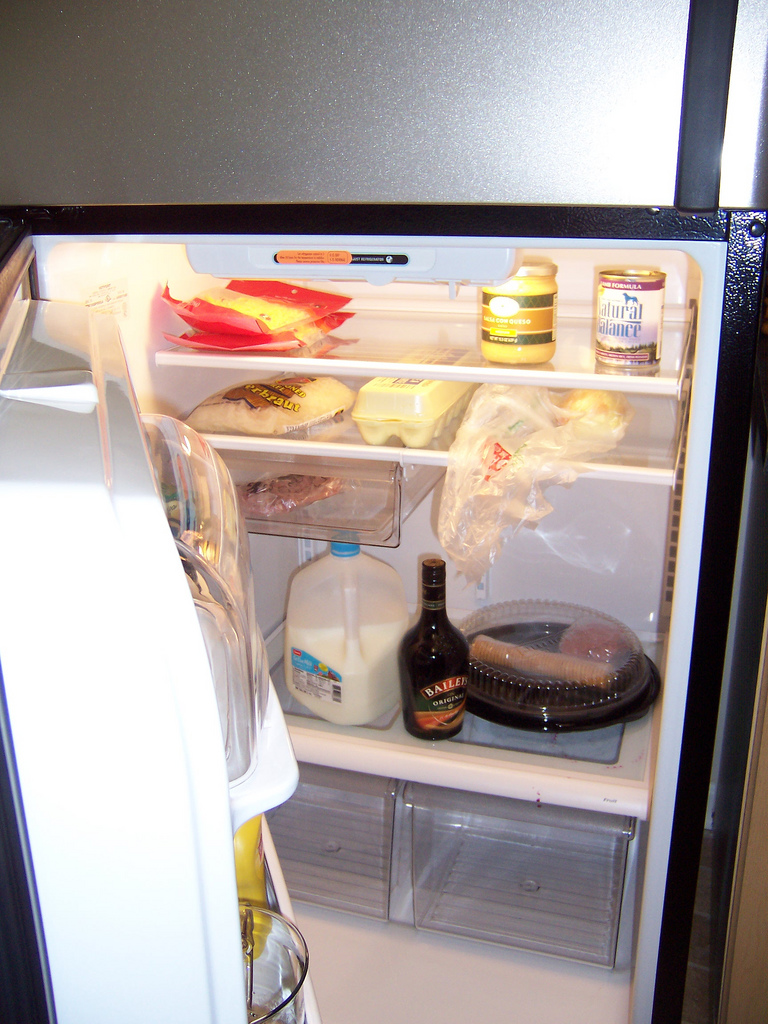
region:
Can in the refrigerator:
[585, 267, 671, 375]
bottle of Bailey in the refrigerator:
[396, 546, 479, 752]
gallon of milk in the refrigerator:
[262, 545, 412, 737]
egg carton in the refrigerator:
[348, 359, 453, 446]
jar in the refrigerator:
[464, 258, 553, 372]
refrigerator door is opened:
[2, 211, 704, 796]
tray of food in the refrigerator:
[453, 588, 654, 754]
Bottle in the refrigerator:
[390, 539, 495, 756]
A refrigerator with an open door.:
[0, 202, 764, 1020]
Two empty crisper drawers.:
[263, 759, 631, 966]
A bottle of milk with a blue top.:
[280, 539, 405, 721]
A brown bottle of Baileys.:
[393, 554, 466, 737]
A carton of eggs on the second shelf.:
[348, 340, 478, 444]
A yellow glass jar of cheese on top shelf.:
[477, 260, 554, 358]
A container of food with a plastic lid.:
[458, 596, 656, 728]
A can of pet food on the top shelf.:
[594, 266, 663, 365]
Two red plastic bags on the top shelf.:
[162, 279, 354, 352]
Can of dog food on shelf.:
[594, 274, 664, 370]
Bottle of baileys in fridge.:
[407, 559, 483, 744]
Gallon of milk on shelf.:
[278, 553, 416, 741]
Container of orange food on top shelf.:
[480, 276, 560, 367]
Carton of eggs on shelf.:
[361, 357, 466, 443]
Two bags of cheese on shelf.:
[189, 271, 336, 369]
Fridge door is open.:
[6, 247, 594, 784]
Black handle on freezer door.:
[672, 27, 737, 211]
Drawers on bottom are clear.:
[286, 781, 614, 954]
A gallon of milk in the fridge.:
[290, 542, 406, 729]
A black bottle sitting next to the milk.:
[408, 551, 473, 739]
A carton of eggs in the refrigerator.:
[358, 350, 465, 447]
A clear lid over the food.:
[477, 602, 643, 701]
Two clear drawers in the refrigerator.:
[295, 783, 660, 961]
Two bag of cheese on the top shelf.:
[178, 283, 337, 352]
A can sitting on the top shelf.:
[579, 268, 673, 375]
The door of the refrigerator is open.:
[21, 582, 295, 1021]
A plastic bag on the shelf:
[466, 385, 634, 480]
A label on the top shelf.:
[259, 247, 407, 287]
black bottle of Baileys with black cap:
[399, 559, 467, 738]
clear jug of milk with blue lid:
[285, 539, 405, 724]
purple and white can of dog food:
[594, 268, 664, 368]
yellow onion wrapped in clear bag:
[560, 388, 626, 442]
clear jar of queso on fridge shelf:
[480, 261, 556, 359]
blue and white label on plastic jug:
[287, 645, 341, 705]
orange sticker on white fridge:
[276, 249, 350, 266]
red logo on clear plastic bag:
[481, 437, 511, 483]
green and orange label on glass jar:
[478, 290, 556, 345]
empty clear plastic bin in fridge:
[399, 777, 637, 978]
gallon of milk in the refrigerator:
[280, 538, 419, 726]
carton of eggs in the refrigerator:
[350, 334, 479, 452]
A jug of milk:
[268, 504, 438, 742]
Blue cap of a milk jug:
[303, 516, 377, 568]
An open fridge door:
[0, 213, 384, 1013]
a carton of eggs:
[349, 377, 468, 446]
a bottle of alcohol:
[396, 555, 470, 742]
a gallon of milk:
[284, 534, 411, 726]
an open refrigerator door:
[4, 220, 766, 1022]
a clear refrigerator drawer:
[262, 757, 401, 919]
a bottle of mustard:
[231, 817, 269, 951]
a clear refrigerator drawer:
[216, 443, 436, 545]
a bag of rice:
[182, 373, 356, 435]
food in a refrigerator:
[278, 532, 418, 734]